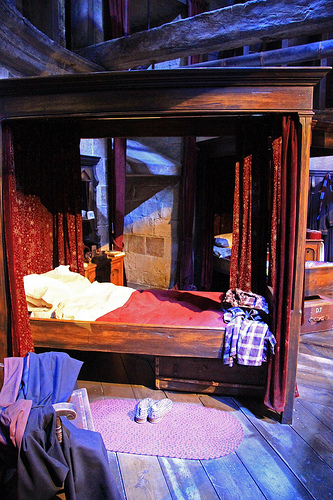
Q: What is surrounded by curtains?
A: Bed.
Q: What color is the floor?
A: Brown.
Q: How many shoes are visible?
A: Two.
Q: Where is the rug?
A: On the Floor.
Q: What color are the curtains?
A: Red.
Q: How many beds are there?
A: One.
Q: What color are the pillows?
A: White.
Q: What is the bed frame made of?
A: Wood.